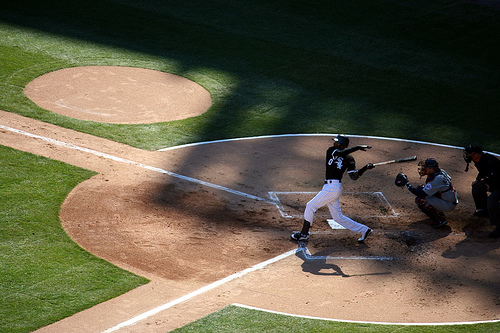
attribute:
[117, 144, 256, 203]
line — white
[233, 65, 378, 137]
field — green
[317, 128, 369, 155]
helmet — black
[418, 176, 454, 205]
uniform — gray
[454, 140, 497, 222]
umpire — watching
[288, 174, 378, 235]
pants — stripes, white, whites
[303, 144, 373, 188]
jersey — black